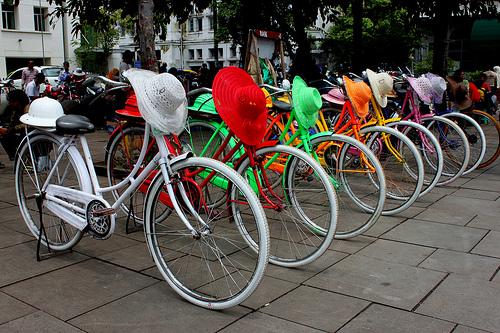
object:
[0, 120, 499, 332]
ground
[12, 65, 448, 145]
hat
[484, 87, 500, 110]
backpack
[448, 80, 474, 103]
shirt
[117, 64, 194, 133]
plane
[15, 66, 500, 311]
bicycle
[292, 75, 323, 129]
green hat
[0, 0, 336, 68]
buildings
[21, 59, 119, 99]
people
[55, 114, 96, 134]
seat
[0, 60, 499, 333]
row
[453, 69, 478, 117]
man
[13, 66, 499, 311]
line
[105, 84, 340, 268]
bicycle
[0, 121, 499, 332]
sidewalk